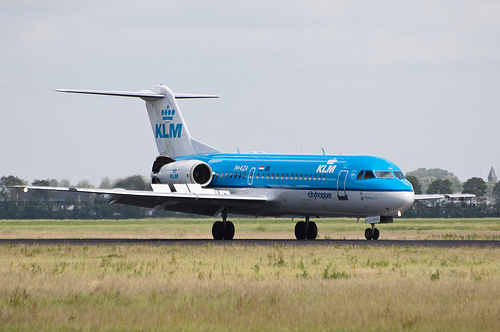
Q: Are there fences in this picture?
A: No, there are no fences.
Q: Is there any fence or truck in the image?
A: No, there are no fences or trucks.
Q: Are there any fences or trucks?
A: No, there are no fences or trucks.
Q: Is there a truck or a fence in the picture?
A: No, there are no fences or trucks.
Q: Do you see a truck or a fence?
A: No, there are no fences or trucks.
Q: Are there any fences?
A: No, there are no fences.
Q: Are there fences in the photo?
A: No, there are no fences.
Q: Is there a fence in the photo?
A: No, there are no fences.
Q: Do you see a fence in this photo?
A: No, there are no fences.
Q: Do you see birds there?
A: No, there are no birds.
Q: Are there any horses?
A: No, there are no horses.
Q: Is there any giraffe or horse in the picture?
A: No, there are no horses or giraffes.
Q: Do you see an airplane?
A: Yes, there is an airplane.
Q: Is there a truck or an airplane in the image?
A: Yes, there is an airplane.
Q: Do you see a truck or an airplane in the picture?
A: Yes, there is an airplane.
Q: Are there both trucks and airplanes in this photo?
A: No, there is an airplane but no trucks.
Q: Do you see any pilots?
A: No, there are no pilots.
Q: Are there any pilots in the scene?
A: No, there are no pilots.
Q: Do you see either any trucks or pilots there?
A: No, there are no pilots or trucks.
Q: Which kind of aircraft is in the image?
A: The aircraft is an airplane.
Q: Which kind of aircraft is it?
A: The aircraft is an airplane.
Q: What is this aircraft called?
A: This is an airplane.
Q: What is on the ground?
A: The plane is on the ground.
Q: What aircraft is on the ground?
A: The aircraft is an airplane.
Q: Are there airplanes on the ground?
A: Yes, there is an airplane on the ground.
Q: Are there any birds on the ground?
A: No, there is an airplane on the ground.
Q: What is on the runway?
A: The airplane is on the runway.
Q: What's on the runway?
A: The airplane is on the runway.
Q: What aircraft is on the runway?
A: The aircraft is an airplane.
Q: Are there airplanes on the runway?
A: Yes, there is an airplane on the runway.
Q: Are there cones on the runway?
A: No, there is an airplane on the runway.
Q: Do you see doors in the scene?
A: Yes, there is a door.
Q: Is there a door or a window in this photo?
A: Yes, there is a door.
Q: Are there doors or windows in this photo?
A: Yes, there is a door.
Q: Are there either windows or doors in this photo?
A: Yes, there is a door.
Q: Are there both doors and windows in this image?
A: Yes, there are both a door and a window.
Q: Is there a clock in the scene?
A: No, there are no clocks.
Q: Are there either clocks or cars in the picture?
A: No, there are no clocks or cars.